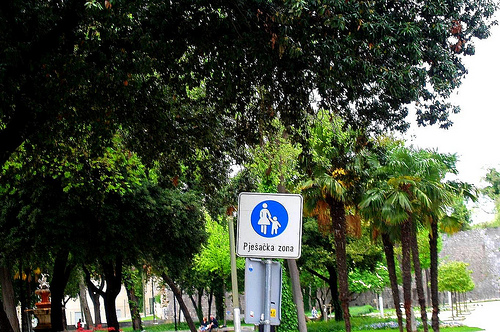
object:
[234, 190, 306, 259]
sign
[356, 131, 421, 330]
tree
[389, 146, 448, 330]
tree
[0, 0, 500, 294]
leaves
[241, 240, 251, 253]
letters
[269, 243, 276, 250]
letters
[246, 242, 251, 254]
letters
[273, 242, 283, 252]
letters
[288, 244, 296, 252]
letters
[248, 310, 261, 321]
stickers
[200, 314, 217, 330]
people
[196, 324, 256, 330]
bench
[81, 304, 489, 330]
grass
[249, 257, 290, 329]
pole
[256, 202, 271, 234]
lady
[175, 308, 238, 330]
people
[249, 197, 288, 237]
blue circle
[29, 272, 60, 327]
water fountain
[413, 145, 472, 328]
palm tree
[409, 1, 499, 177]
sky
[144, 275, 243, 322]
building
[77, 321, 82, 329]
flower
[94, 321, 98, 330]
flower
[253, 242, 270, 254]
letters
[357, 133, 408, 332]
palms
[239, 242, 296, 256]
polish language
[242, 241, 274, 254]
word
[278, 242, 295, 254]
word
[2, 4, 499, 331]
branches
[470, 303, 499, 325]
water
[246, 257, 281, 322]
sign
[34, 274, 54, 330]
fountain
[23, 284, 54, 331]
water fountain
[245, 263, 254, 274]
sticker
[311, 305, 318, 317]
woman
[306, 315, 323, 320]
bench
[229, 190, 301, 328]
signs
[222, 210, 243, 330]
pole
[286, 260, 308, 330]
pole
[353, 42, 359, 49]
leaf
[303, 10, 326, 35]
leaf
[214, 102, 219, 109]
leaf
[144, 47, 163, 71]
leaf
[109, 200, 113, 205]
leaf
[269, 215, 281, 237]
child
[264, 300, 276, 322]
stickers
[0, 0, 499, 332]
tree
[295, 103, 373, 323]
palm trees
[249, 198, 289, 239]
circle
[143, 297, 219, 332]
bench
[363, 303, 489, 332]
stone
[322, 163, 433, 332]
tall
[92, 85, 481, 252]
green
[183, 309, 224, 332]
relaxing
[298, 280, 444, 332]
clear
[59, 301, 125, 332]
red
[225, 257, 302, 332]
box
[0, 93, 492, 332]
park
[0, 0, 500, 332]
distance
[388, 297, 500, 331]
road